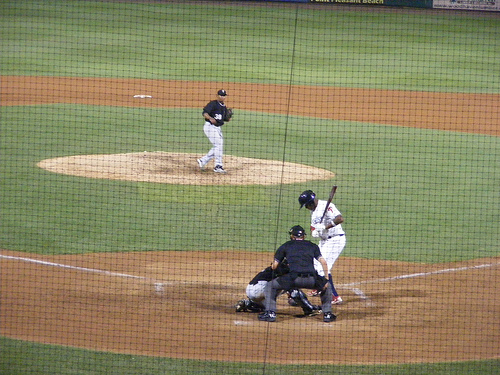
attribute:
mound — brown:
[36, 143, 334, 197]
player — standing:
[298, 187, 360, 308]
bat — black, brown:
[315, 182, 341, 232]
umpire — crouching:
[264, 222, 339, 331]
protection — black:
[280, 240, 325, 286]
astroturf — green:
[39, 10, 374, 78]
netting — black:
[1, 4, 68, 360]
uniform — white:
[309, 201, 345, 267]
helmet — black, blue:
[292, 188, 320, 203]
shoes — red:
[323, 289, 342, 308]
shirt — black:
[270, 243, 322, 272]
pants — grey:
[268, 274, 335, 319]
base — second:
[125, 88, 161, 105]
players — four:
[165, 85, 373, 344]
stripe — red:
[323, 204, 337, 215]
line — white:
[336, 280, 379, 314]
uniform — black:
[200, 102, 236, 172]